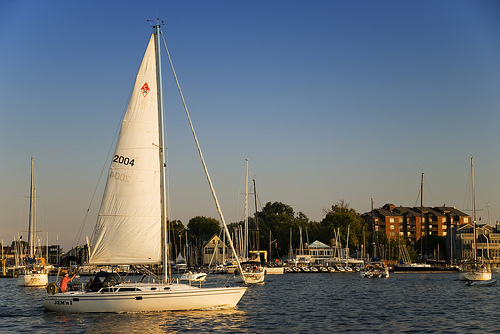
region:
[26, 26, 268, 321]
A sail boat on water.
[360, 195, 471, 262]
A multi story building.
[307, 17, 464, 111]
a section of clear blue sky.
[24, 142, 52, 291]
a sail boat on water.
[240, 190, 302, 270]
A large leafy green tree.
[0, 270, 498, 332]
a large body of water.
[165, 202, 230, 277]
two leafy green trees.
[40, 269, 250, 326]
a boat on water.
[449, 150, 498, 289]
a sail boat on water.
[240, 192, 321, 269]
a tree near water.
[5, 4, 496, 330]
port scene as a seaside town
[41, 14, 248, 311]
white sail boat under sail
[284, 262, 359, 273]
motor boats docked at a marina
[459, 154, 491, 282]
docked sailboat in a harbor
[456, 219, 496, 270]
building near the water in a harbor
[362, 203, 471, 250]
red brick apartment building near the harbor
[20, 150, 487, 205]
masts above boats in the harbor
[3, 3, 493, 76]
dark blue sky over the harbor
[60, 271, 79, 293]
sailor with orange long sleeve shirt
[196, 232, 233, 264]
yellow building with black shutters on the windows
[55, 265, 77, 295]
person on white sailboat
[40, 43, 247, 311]
white sailboat in the water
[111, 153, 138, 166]
black numbers on white sail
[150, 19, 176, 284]
mast on the sailboat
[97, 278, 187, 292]
cabin on the white sailboat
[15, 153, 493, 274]
masts of other boats in the harbor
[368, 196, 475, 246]
brick building with black roof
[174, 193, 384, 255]
trees on the shoreline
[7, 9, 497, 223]
blue sky fading to white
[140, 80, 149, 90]
red triangle on white sail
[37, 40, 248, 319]
white sail boat in bay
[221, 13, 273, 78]
white clouds in blue sky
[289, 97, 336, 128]
white clouds in blue sky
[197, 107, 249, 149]
white clouds in blue sky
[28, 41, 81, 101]
white clouds in blue sky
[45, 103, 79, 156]
white clouds in blue sky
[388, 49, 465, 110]
white clouds in blue sky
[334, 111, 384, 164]
white clouds in blue sky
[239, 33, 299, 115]
white clouds in blue sky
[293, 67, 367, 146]
white clouds in blue sky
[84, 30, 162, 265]
the white black and red sail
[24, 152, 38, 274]
the tall metal mast of the sailboat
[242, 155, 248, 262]
the tall metal mast of the sailboat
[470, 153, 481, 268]
the tall metal mast of the sailboat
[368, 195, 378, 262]
the tall metal mast of the sailboat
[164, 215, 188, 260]
the dark green tree in the distance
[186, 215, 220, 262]
the dark green tree in the distance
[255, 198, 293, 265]
the dark green tree in the distance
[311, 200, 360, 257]
the dark green tree in the distance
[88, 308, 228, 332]
the reflection of the boat